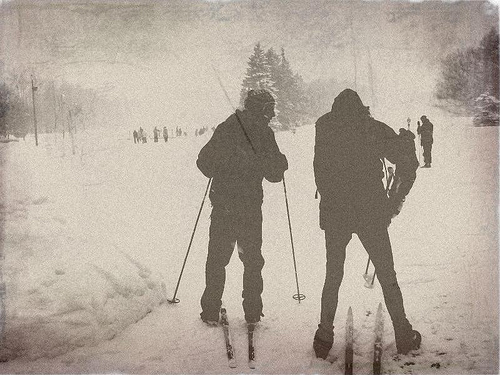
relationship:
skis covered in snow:
[342, 298, 390, 374] [410, 246, 497, 374]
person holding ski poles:
[309, 83, 434, 358] [356, 253, 384, 300]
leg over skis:
[309, 232, 356, 344] [342, 298, 390, 374]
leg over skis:
[362, 228, 414, 343] [342, 298, 390, 374]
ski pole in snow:
[159, 176, 214, 313] [0, 306, 227, 374]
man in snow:
[414, 113, 437, 171] [410, 246, 497, 374]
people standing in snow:
[129, 126, 209, 146] [17, 136, 198, 250]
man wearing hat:
[169, 83, 297, 336] [243, 88, 276, 119]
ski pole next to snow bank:
[159, 176, 214, 313] [3, 164, 172, 364]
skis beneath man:
[342, 298, 390, 374] [309, 83, 434, 358]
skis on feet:
[218, 297, 263, 374] [181, 291, 267, 326]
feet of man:
[181, 291, 267, 326] [169, 83, 297, 336]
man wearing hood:
[309, 83, 434, 358] [329, 88, 365, 118]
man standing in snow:
[414, 113, 437, 171] [410, 246, 497, 374]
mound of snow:
[3, 164, 172, 364] [0, 306, 227, 374]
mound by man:
[3, 164, 172, 364] [169, 83, 297, 336]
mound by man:
[309, 83, 434, 358] [414, 113, 437, 171]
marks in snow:
[429, 312, 496, 374] [410, 246, 497, 374]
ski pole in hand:
[159, 176, 214, 313] [207, 166, 215, 174]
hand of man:
[207, 166, 215, 174] [169, 83, 297, 336]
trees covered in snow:
[235, 40, 319, 131] [410, 246, 497, 374]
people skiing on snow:
[129, 126, 209, 146] [410, 246, 497, 374]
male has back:
[309, 83, 434, 358] [311, 114, 400, 254]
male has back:
[169, 83, 297, 336] [211, 114, 266, 236]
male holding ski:
[309, 83, 434, 358] [380, 164, 403, 209]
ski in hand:
[380, 164, 403, 209] [392, 196, 408, 219]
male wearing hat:
[169, 83, 297, 336] [243, 88, 276, 119]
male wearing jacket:
[309, 83, 434, 358] [312, 113, 400, 239]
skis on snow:
[342, 298, 390, 374] [410, 246, 497, 374]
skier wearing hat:
[169, 83, 297, 336] [243, 88, 276, 119]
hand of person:
[207, 166, 215, 174] [169, 83, 297, 336]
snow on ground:
[410, 246, 497, 374] [66, 159, 497, 374]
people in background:
[129, 126, 209, 146] [14, 128, 215, 146]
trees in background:
[235, 40, 319, 131] [14, 128, 215, 146]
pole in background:
[26, 75, 51, 149] [14, 128, 215, 146]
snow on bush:
[410, 246, 497, 374] [465, 94, 498, 128]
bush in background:
[465, 94, 498, 128] [14, 128, 215, 146]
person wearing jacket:
[309, 83, 434, 358] [312, 113, 400, 239]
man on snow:
[414, 113, 437, 171] [410, 246, 497, 374]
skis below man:
[218, 297, 263, 374] [169, 83, 297, 336]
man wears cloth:
[414, 113, 437, 171] [425, 121, 434, 137]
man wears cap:
[169, 83, 297, 336] [243, 88, 276, 119]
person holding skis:
[309, 83, 434, 358] [342, 298, 390, 374]